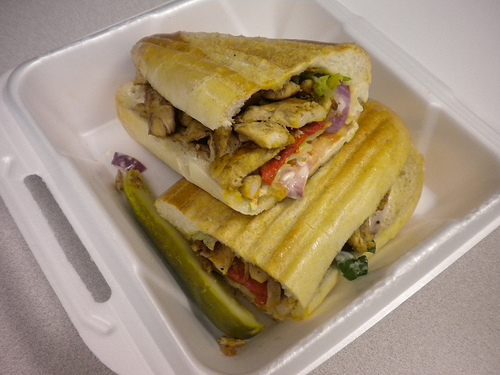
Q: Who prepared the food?
A: A cook.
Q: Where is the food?
A: In a box.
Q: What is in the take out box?
A: A sandwich.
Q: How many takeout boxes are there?
A: One.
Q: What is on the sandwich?
A: Chicken.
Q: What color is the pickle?
A: Green.